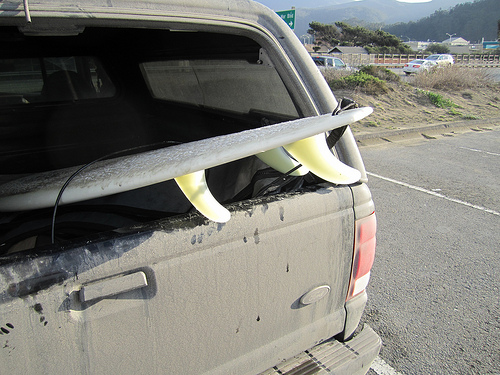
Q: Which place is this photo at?
A: It is at the parking lot.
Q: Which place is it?
A: It is a parking lot.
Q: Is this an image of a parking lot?
A: Yes, it is showing a parking lot.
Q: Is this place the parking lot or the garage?
A: It is the parking lot.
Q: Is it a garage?
A: No, it is a parking lot.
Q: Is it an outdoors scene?
A: Yes, it is outdoors.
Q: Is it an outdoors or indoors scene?
A: It is outdoors.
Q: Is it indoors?
A: No, it is outdoors.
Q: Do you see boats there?
A: No, there are no boats.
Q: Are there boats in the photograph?
A: No, there are no boats.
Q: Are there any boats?
A: No, there are no boats.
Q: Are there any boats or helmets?
A: No, there are no boats or helmets.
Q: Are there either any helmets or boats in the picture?
A: No, there are no boats or helmets.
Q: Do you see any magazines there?
A: No, there are no magazines.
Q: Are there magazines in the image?
A: No, there are no magazines.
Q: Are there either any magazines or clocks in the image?
A: No, there are no magazines or clocks.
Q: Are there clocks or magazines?
A: No, there are no magazines or clocks.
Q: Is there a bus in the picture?
A: No, there are no buses.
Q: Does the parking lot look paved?
A: Yes, the parking lot is paved.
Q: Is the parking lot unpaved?
A: No, the parking lot is paved.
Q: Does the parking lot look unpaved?
A: No, the parking lot is paved.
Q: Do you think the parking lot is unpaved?
A: No, the parking lot is paved.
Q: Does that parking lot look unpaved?
A: No, the parking lot is paved.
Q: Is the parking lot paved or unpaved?
A: The parking lot is paved.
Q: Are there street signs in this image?
A: Yes, there is a street sign.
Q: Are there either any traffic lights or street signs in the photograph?
A: Yes, there is a street sign.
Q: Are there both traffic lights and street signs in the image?
A: No, there is a street sign but no traffic lights.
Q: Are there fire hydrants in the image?
A: No, there are no fire hydrants.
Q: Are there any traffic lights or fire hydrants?
A: No, there are no fire hydrants or traffic lights.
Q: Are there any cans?
A: No, there are no cans.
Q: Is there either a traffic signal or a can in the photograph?
A: No, there are no cans or traffic lights.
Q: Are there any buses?
A: No, there are no buses.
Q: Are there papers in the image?
A: No, there are no papers.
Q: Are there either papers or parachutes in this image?
A: No, there are no papers or parachutes.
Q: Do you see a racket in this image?
A: No, there are no rackets.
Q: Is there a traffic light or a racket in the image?
A: No, there are no rackets or traffic lights.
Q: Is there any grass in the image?
A: Yes, there is grass.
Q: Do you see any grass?
A: Yes, there is grass.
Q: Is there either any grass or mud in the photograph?
A: Yes, there is grass.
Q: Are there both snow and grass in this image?
A: No, there is grass but no snow.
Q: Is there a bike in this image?
A: No, there are no bikes.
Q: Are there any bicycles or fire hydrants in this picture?
A: No, there are no bicycles or fire hydrants.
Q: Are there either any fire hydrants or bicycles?
A: No, there are no bicycles or fire hydrants.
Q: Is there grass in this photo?
A: Yes, there is grass.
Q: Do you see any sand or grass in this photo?
A: Yes, there is grass.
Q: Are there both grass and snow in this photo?
A: No, there is grass but no snow.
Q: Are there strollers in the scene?
A: No, there are no strollers.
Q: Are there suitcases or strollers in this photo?
A: No, there are no strollers or suitcases.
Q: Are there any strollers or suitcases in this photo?
A: No, there are no strollers or suitcases.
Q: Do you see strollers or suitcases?
A: No, there are no strollers or suitcases.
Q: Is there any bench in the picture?
A: No, there are no benches.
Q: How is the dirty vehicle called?
A: The vehicle is a SUV.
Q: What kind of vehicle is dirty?
A: The vehicle is a SUV.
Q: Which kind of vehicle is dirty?
A: The vehicle is a SUV.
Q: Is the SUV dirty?
A: Yes, the SUV is dirty.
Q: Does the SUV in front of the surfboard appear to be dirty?
A: Yes, the SUV is dirty.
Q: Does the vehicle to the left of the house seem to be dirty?
A: Yes, the SUV is dirty.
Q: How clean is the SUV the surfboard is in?
A: The SUV is dirty.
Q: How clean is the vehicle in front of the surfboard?
A: The SUV is dirty.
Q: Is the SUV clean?
A: No, the SUV is dirty.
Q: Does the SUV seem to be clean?
A: No, the SUV is dirty.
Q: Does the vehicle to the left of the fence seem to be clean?
A: No, the SUV is dirty.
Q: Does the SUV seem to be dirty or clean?
A: The SUV is dirty.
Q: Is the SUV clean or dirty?
A: The SUV is dirty.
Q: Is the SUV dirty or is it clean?
A: The SUV is dirty.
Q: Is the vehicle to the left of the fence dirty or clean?
A: The SUV is dirty.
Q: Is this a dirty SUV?
A: Yes, this is a dirty SUV.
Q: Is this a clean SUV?
A: No, this is a dirty SUV.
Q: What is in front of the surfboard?
A: The SUV is in front of the surfboard.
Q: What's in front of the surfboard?
A: The SUV is in front of the surfboard.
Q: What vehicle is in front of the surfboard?
A: The vehicle is a SUV.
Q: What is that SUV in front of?
A: The SUV is in front of the surfboard.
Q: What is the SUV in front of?
A: The SUV is in front of the surfboard.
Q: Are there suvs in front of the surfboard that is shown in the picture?
A: Yes, there is a SUV in front of the surfboard.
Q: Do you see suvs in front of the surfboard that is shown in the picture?
A: Yes, there is a SUV in front of the surfboard.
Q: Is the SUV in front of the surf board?
A: Yes, the SUV is in front of the surf board.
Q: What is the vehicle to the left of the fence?
A: The vehicle is a SUV.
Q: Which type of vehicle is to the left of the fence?
A: The vehicle is a SUV.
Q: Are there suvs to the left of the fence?
A: Yes, there is a SUV to the left of the fence.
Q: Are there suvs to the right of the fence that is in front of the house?
A: No, the SUV is to the left of the fence.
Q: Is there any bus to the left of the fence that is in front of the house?
A: No, there is a SUV to the left of the fence.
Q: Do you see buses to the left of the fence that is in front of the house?
A: No, there is a SUV to the left of the fence.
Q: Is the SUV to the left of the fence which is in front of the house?
A: Yes, the SUV is to the left of the fence.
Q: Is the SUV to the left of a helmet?
A: No, the SUV is to the left of the fence.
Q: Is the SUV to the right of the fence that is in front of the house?
A: No, the SUV is to the left of the fence.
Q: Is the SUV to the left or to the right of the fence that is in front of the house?
A: The SUV is to the left of the fence.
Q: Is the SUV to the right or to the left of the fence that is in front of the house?
A: The SUV is to the left of the fence.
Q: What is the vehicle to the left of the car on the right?
A: The vehicle is a SUV.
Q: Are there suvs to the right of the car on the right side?
A: No, the SUV is to the left of the car.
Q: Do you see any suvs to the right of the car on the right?
A: No, the SUV is to the left of the car.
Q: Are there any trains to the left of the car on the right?
A: No, there is a SUV to the left of the car.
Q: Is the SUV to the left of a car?
A: Yes, the SUV is to the left of a car.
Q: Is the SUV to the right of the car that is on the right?
A: No, the SUV is to the left of the car.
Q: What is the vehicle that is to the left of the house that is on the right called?
A: The vehicle is a SUV.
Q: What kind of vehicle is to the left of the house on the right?
A: The vehicle is a SUV.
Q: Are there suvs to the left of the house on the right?
A: Yes, there is a SUV to the left of the house.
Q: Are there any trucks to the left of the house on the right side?
A: No, there is a SUV to the left of the house.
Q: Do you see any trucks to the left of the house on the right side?
A: No, there is a SUV to the left of the house.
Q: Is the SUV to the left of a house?
A: Yes, the SUV is to the left of a house.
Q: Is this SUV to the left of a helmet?
A: No, the SUV is to the left of a house.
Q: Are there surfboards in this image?
A: Yes, there is a surfboard.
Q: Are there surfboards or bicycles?
A: Yes, there is a surfboard.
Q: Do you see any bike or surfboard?
A: Yes, there is a surfboard.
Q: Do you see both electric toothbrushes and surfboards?
A: No, there is a surfboard but no electric toothbrushes.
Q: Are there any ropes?
A: No, there are no ropes.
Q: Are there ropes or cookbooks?
A: No, there are no ropes or cookbooks.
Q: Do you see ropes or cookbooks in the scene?
A: No, there are no ropes or cookbooks.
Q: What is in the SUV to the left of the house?
A: The surfboard is in the SUV.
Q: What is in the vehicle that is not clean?
A: The surfboard is in the SUV.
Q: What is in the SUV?
A: The surfboard is in the SUV.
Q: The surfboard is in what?
A: The surfboard is in the SUV.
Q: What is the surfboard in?
A: The surfboard is in the SUV.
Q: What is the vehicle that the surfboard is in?
A: The vehicle is a SUV.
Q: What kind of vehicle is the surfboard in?
A: The surfboard is in the SUV.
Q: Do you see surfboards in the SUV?
A: Yes, there is a surfboard in the SUV.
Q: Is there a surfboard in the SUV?
A: Yes, there is a surfboard in the SUV.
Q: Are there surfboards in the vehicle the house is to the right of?
A: Yes, there is a surfboard in the SUV.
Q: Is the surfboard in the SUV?
A: Yes, the surfboard is in the SUV.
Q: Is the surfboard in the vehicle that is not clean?
A: Yes, the surfboard is in the SUV.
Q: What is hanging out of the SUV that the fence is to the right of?
A: The surfboard is hanging out of the SUV.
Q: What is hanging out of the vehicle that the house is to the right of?
A: The surfboard is hanging out of the SUV.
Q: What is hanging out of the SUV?
A: The surfboard is hanging out of the SUV.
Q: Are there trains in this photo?
A: No, there are no trains.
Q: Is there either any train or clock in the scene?
A: No, there are no trains or clocks.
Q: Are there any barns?
A: No, there are no barns.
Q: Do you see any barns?
A: No, there are no barns.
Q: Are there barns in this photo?
A: No, there are no barns.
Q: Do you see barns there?
A: No, there are no barns.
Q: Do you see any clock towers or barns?
A: No, there are no barns or clock towers.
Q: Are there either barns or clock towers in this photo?
A: No, there are no barns or clock towers.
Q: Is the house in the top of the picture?
A: Yes, the house is in the top of the image.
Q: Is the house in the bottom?
A: No, the house is in the top of the image.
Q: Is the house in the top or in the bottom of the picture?
A: The house is in the top of the image.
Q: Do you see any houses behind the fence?
A: Yes, there is a house behind the fence.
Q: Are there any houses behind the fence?
A: Yes, there is a house behind the fence.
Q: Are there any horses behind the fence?
A: No, there is a house behind the fence.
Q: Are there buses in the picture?
A: No, there are no buses.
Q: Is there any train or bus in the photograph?
A: No, there are no buses or trains.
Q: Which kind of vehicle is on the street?
A: The vehicle is a car.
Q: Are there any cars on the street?
A: Yes, there is a car on the street.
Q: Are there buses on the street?
A: No, there is a car on the street.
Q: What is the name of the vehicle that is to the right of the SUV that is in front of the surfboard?
A: The vehicle is a car.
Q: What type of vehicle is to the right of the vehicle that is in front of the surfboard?
A: The vehicle is a car.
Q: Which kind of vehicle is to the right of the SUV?
A: The vehicle is a car.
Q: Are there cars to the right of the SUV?
A: Yes, there is a car to the right of the SUV.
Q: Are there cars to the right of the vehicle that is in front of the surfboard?
A: Yes, there is a car to the right of the SUV.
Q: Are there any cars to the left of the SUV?
A: No, the car is to the right of the SUV.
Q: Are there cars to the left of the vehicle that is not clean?
A: No, the car is to the right of the SUV.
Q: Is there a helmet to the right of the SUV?
A: No, there is a car to the right of the SUV.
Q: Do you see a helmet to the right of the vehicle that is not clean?
A: No, there is a car to the right of the SUV.